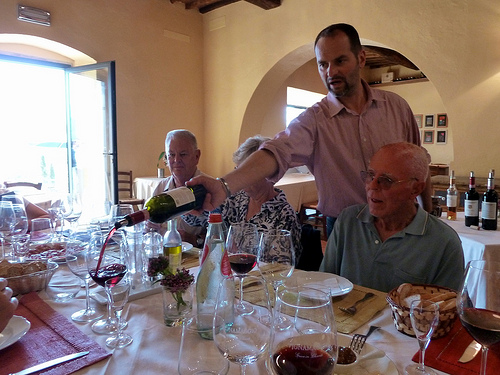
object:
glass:
[212, 276, 268, 375]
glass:
[88, 231, 131, 334]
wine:
[274, 344, 334, 375]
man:
[330, 142, 464, 280]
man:
[204, 25, 426, 281]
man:
[150, 129, 211, 243]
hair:
[167, 129, 193, 138]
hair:
[319, 24, 356, 35]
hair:
[381, 142, 427, 162]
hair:
[235, 136, 265, 156]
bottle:
[117, 184, 207, 224]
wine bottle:
[147, 186, 210, 222]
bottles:
[164, 217, 182, 271]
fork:
[350, 319, 376, 352]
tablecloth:
[117, 294, 178, 374]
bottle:
[464, 172, 479, 227]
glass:
[141, 230, 163, 281]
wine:
[88, 227, 126, 286]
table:
[0, 220, 500, 374]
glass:
[12, 235, 30, 263]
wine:
[90, 210, 146, 235]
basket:
[387, 284, 460, 339]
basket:
[7, 263, 59, 296]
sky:
[283, 85, 320, 109]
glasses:
[125, 217, 145, 284]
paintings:
[435, 113, 448, 144]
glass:
[0, 200, 14, 255]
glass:
[459, 261, 500, 375]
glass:
[178, 318, 227, 375]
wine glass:
[61, 230, 104, 325]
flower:
[160, 267, 195, 291]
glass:
[161, 286, 193, 324]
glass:
[108, 205, 134, 244]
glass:
[105, 280, 131, 347]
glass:
[409, 302, 439, 375]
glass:
[218, 220, 260, 312]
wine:
[227, 254, 254, 274]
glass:
[50, 206, 63, 239]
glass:
[61, 195, 82, 239]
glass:
[259, 229, 294, 330]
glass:
[3, 196, 27, 251]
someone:
[222, 135, 299, 264]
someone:
[0, 184, 52, 234]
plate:
[290, 271, 354, 297]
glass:
[270, 291, 334, 375]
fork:
[336, 292, 374, 315]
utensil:
[458, 341, 479, 362]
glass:
[32, 218, 55, 243]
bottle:
[446, 172, 457, 221]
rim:
[90, 230, 123, 236]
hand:
[183, 175, 228, 211]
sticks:
[132, 224, 139, 277]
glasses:
[378, 179, 392, 189]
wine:
[467, 308, 500, 347]